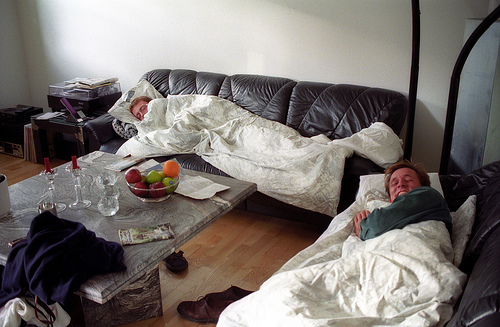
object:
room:
[3, 2, 499, 326]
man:
[128, 95, 331, 171]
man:
[271, 162, 452, 327]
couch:
[80, 68, 406, 217]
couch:
[450, 168, 500, 327]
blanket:
[116, 94, 404, 216]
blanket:
[218, 189, 477, 326]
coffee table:
[0, 150, 258, 327]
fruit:
[162, 160, 181, 179]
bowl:
[127, 183, 178, 202]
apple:
[125, 168, 142, 183]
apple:
[132, 181, 148, 197]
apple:
[149, 182, 168, 199]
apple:
[145, 169, 164, 183]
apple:
[162, 177, 179, 194]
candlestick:
[39, 171, 66, 213]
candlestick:
[65, 164, 93, 211]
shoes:
[175, 285, 252, 323]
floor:
[0, 156, 322, 327]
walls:
[22, 0, 488, 196]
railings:
[402, 1, 421, 167]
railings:
[439, 6, 498, 167]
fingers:
[366, 210, 371, 218]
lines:
[166, 69, 172, 93]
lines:
[192, 70, 199, 94]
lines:
[284, 80, 299, 125]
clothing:
[0, 212, 125, 308]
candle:
[44, 157, 50, 173]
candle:
[72, 156, 77, 169]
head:
[128, 96, 151, 120]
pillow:
[106, 78, 166, 126]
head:
[382, 161, 430, 204]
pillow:
[358, 173, 442, 199]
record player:
[47, 76, 122, 113]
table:
[48, 112, 84, 161]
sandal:
[160, 250, 189, 273]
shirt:
[359, 187, 452, 240]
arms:
[83, 113, 119, 152]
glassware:
[96, 170, 121, 217]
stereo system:
[0, 141, 23, 160]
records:
[22, 124, 25, 162]